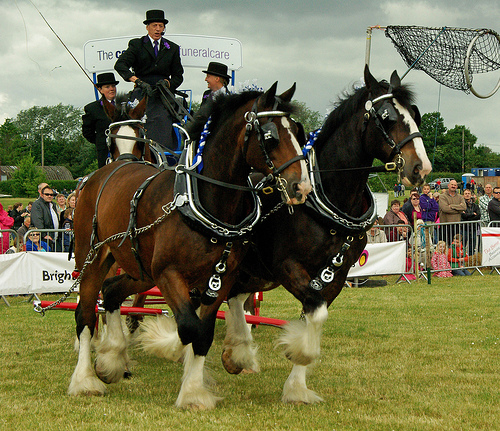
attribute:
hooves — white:
[64, 369, 115, 408]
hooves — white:
[95, 345, 132, 386]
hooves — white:
[171, 383, 225, 415]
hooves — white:
[176, 368, 224, 410]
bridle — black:
[171, 127, 271, 245]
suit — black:
[81, 97, 135, 166]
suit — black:
[114, 31, 187, 94]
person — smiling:
[179, 59, 240, 154]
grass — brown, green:
[6, 259, 497, 427]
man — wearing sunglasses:
[30, 185, 60, 244]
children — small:
[431, 231, 467, 281]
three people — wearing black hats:
[82, 6, 231, 166]